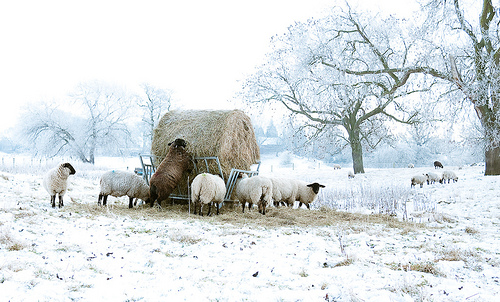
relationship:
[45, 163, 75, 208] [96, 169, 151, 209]
herd next to sheep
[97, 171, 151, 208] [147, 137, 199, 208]
sheep next to sheep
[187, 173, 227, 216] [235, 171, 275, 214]
sheep next to sheep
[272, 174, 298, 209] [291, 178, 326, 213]
sheep next to sheep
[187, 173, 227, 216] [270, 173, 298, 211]
sheep next to sheep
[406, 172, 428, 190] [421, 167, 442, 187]
sheep next to sheep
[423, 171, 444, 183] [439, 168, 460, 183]
sheep next to sheep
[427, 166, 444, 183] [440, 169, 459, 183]
sheep next to sheep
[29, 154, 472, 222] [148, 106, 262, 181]
sheep gathered around bale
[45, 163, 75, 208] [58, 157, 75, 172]
herd has face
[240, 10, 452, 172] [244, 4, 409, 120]
tree covered with snow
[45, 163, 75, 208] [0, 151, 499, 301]
herd standing in snow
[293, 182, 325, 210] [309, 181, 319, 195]
sheep has face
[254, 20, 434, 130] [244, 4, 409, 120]
branches has snow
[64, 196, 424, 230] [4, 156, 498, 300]
hay dropped on ground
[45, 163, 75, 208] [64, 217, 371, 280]
herd standing on snow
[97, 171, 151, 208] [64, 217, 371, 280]
sheep standing on snow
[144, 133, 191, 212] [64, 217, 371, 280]
sheep standing on snow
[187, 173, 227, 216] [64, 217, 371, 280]
sheep standing on snow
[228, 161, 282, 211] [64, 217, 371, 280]
sheep standing on snow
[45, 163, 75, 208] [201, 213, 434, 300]
herd standing on ground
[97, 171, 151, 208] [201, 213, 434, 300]
sheep standing on ground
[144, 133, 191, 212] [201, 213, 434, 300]
sheep standing on ground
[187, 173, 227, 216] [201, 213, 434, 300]
sheep standing on ground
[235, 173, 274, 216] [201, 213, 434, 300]
sheep standing on ground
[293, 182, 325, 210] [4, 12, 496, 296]
sheep standing outside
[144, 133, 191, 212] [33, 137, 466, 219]
sheep standing in herd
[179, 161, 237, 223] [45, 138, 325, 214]
sheep standing in herd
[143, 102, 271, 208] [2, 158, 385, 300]
hay sitting on ground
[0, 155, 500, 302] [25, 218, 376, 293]
snow on top of ground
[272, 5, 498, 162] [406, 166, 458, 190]
trees next to sheep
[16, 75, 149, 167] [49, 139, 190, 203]
trees next to sheep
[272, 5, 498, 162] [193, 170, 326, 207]
trees next to sheep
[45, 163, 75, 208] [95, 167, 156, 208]
herd next to sheep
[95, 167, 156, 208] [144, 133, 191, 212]
sheep next to sheep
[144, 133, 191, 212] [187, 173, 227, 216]
sheep next to sheep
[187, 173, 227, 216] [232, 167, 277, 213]
sheep next to sheep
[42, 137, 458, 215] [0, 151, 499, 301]
sheep standing in snow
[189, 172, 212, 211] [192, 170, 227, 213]
rear end on sheep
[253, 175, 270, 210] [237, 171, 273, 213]
rear end on sheep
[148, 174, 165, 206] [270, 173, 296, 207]
rear end on sheep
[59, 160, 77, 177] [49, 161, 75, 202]
head turned on sheep